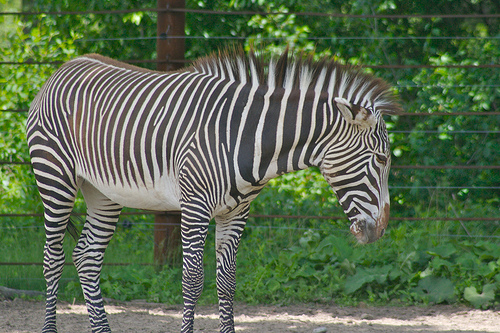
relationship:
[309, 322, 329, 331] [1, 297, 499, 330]
rock on dirt ground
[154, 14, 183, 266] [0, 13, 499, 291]
pole supports fence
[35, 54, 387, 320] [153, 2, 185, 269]
zebra obstructs pole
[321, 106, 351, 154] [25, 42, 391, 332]
ear of zebra